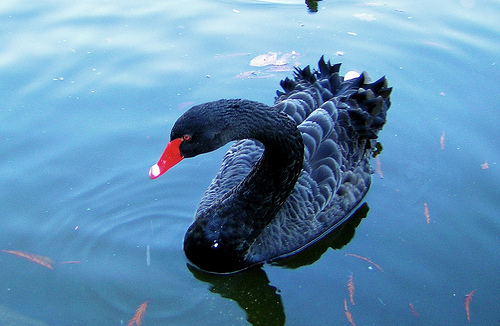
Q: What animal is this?
A: Swan.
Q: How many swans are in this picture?
A: 1.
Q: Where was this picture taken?
A: Pond.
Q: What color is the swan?
A: Black.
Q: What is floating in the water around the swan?
A: Leaves.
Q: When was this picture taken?
A: Daytime.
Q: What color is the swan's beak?
A: Red.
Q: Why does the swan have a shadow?
A: It's sunny.